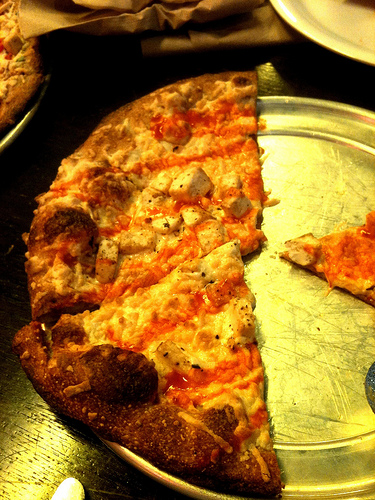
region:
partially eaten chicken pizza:
[12, 73, 373, 487]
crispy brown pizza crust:
[8, 317, 294, 498]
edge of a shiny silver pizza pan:
[263, 2, 371, 68]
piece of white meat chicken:
[283, 231, 321, 274]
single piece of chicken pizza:
[10, 236, 300, 499]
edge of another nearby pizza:
[0, 1, 57, 166]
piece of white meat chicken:
[162, 163, 217, 205]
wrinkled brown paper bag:
[12, 1, 296, 57]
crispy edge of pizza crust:
[19, 110, 130, 318]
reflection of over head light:
[0, 377, 106, 497]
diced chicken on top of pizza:
[144, 171, 244, 228]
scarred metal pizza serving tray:
[122, 96, 372, 496]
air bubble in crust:
[86, 340, 155, 408]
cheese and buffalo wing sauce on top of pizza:
[129, 265, 280, 411]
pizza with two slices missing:
[31, 98, 373, 492]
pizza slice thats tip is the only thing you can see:
[283, 213, 372, 303]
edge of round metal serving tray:
[267, 3, 373, 65]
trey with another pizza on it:
[0, 0, 47, 148]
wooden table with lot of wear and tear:
[0, 148, 121, 498]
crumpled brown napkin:
[7, 0, 283, 50]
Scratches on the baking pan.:
[264, 301, 365, 426]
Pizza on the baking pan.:
[110, 143, 251, 354]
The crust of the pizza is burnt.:
[56, 352, 154, 422]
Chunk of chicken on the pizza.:
[154, 173, 237, 219]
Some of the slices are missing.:
[67, 105, 339, 350]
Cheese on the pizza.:
[105, 160, 220, 240]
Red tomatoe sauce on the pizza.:
[130, 242, 201, 312]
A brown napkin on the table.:
[67, 13, 136, 59]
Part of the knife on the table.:
[53, 471, 98, 498]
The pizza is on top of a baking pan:
[73, 67, 373, 371]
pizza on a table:
[2, 45, 323, 490]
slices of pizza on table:
[0, 43, 287, 400]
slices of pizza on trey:
[22, 65, 344, 497]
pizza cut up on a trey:
[43, 45, 364, 499]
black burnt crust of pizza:
[53, 385, 158, 436]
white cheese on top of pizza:
[146, 250, 248, 380]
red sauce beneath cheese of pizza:
[139, 283, 208, 348]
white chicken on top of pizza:
[222, 311, 260, 335]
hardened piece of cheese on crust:
[246, 445, 270, 479]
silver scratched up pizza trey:
[285, 292, 359, 406]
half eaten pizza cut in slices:
[4, 58, 295, 498]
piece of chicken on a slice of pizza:
[187, 235, 250, 296]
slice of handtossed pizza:
[8, 233, 333, 497]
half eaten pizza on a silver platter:
[12, 74, 370, 496]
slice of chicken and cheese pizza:
[17, 64, 291, 302]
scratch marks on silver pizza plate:
[273, 303, 353, 403]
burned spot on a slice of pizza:
[41, 199, 101, 274]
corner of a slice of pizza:
[273, 233, 329, 279]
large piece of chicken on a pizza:
[167, 157, 209, 207]